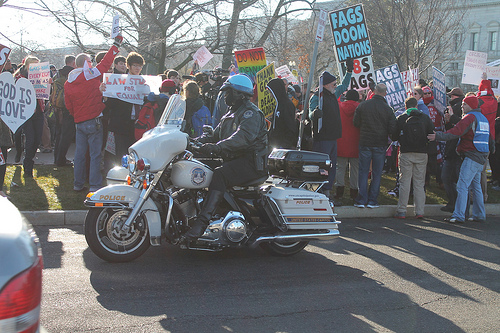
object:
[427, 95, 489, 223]
person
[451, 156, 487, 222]
pants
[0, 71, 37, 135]
sign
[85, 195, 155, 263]
tire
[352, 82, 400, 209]
man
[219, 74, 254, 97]
helmet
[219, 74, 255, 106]
head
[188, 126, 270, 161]
bars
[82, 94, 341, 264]
bike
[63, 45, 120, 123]
jacket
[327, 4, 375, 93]
sign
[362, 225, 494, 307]
cast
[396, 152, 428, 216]
pants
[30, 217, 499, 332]
street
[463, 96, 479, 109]
hat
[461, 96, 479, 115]
head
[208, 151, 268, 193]
pants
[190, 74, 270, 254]
cop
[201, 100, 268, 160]
coat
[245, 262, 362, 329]
green shirt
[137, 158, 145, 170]
red light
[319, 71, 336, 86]
hat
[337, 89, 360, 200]
person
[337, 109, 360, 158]
red coat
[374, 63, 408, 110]
signs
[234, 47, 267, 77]
signs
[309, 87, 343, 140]
jacket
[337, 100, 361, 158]
jacket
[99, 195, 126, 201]
wording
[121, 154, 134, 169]
light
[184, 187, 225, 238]
boot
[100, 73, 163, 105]
sign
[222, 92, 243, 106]
black mask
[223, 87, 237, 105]
face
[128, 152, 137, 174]
headlight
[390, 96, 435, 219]
man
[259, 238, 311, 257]
tire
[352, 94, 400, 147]
jacket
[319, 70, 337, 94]
head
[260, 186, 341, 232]
container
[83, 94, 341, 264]
motorcycle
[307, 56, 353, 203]
person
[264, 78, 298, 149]
person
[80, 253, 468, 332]
shadow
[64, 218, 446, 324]
ground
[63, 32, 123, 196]
man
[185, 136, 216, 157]
handle bars